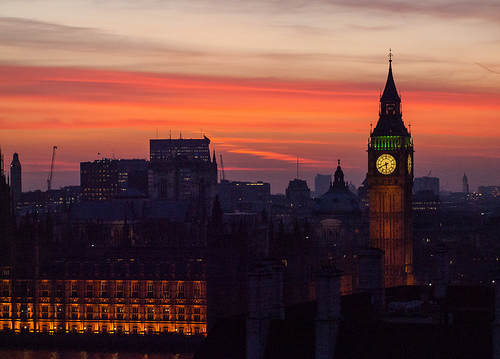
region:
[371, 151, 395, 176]
a clock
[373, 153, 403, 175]
a clock on the building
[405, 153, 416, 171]
clock on the side of the building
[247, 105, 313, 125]
the sky is clear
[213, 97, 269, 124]
the sky is orange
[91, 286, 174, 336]
light on the building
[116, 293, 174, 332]
the building has light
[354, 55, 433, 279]
the building is tall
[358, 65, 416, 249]
a tall building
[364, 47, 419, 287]
a tall clock tower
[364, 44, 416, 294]
a brick gothic tower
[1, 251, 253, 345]
a large victorian era building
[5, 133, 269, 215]
skyline in front of sunset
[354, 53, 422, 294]
an english tower at night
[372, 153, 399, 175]
a small orange clock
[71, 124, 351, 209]
a cluster of buildings during dusk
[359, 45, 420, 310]
Large clock tower looms over the city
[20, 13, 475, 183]
sky is white and orange at sunset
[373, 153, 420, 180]
Tower has multiple clocks near the top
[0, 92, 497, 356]
Large city shown in the image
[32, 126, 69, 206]
Tall crane towers above the skyline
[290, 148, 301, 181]
Antenna pole on top of building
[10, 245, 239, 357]
Building is lit up with lights outside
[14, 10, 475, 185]
Sky is cloudy and hazy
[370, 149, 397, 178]
face of the clock in the tower is lighted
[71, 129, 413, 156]
parliament is illuminated in the evening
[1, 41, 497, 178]
colors of a sunset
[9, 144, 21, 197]
a tower raises in the distance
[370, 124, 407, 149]
green lights over the clock face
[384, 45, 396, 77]
lightening rod on the tower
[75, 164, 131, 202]
lights on in the london buildings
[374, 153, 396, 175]
the time is 6:40 PM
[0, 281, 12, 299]
a window in a building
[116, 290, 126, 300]
a window in a building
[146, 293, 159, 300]
a window in a building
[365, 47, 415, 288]
clock tower is illuminated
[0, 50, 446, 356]
building is illuminated at night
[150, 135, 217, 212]
building is in distance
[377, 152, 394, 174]
illuminated clock face with Roman numerals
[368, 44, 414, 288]
tall clock tower against red sky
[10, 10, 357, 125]
hazy grey clouds above pink-orange streaks of sky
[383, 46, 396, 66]
pointed metal decorative tower top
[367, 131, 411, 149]
eerie green lit barricade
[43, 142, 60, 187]
erect vertical crane head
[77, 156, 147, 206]
squat square building with lights showing through windows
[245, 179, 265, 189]
row of yellow lights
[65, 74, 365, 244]
dark city skyline at dusk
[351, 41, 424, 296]
illuminated tall clock tower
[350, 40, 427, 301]
big ben clock tower